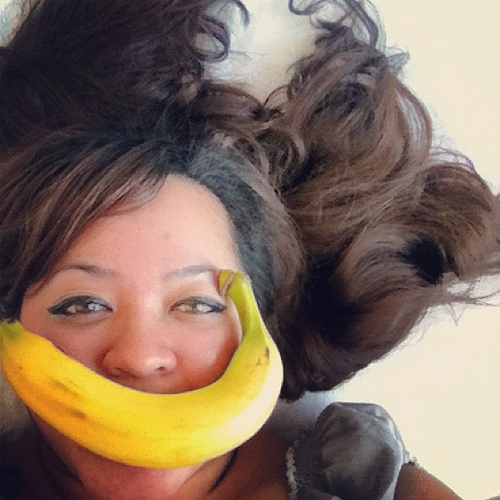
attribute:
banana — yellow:
[42, 373, 244, 442]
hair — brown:
[24, 46, 434, 224]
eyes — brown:
[43, 295, 231, 331]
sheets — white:
[413, 7, 489, 132]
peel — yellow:
[6, 271, 282, 471]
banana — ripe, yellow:
[15, 271, 295, 476]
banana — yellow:
[27, 282, 283, 477]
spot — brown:
[28, 368, 103, 420]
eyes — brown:
[49, 284, 239, 330]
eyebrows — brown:
[165, 261, 219, 279]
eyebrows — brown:
[25, 261, 118, 298]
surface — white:
[6, 0, 498, 498]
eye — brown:
[46, 295, 120, 316]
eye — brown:
[164, 291, 225, 316]